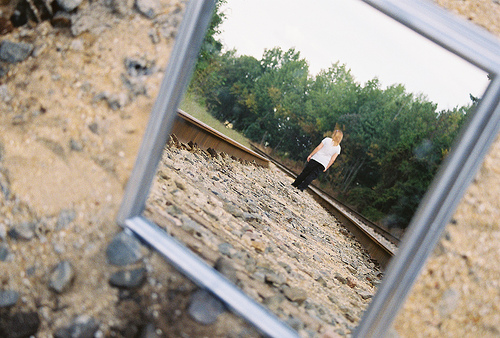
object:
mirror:
[164, 9, 476, 314]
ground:
[0, 78, 82, 223]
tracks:
[165, 104, 402, 260]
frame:
[79, 7, 237, 253]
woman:
[291, 125, 353, 196]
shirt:
[321, 130, 349, 165]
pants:
[298, 147, 323, 196]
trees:
[208, 52, 475, 217]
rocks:
[229, 131, 366, 318]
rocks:
[73, 257, 206, 337]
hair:
[331, 132, 346, 149]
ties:
[183, 118, 355, 300]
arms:
[302, 136, 344, 168]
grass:
[181, 92, 245, 144]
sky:
[221, 4, 484, 96]